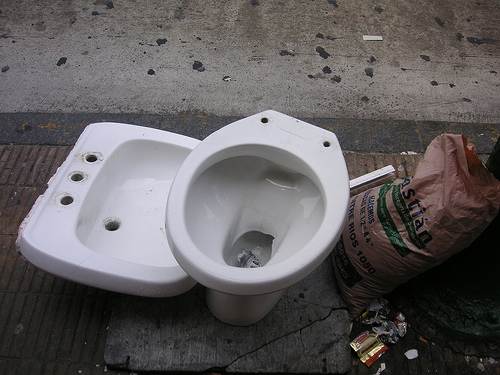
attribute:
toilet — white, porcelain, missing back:
[157, 101, 367, 313]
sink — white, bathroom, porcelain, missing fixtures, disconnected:
[18, 104, 200, 304]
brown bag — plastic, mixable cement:
[342, 126, 493, 310]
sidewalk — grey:
[6, 7, 499, 191]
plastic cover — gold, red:
[349, 329, 392, 365]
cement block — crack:
[214, 294, 345, 372]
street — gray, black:
[6, 28, 495, 109]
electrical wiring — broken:
[421, 329, 435, 351]